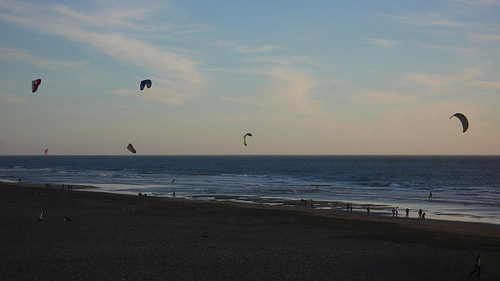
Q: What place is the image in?
A: It is at the beach.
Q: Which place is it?
A: It is a beach.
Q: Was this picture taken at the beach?
A: Yes, it was taken in the beach.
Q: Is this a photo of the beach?
A: Yes, it is showing the beach.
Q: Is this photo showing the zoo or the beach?
A: It is showing the beach.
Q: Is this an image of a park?
A: No, the picture is showing a beach.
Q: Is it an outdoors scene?
A: Yes, it is outdoors.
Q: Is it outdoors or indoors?
A: It is outdoors.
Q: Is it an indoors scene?
A: No, it is outdoors.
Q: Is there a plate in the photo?
A: Yes, there is a plate.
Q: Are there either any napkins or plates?
A: Yes, there is a plate.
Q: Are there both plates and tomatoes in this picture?
A: No, there is a plate but no tomatoes.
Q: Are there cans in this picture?
A: No, there are no cans.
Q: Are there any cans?
A: No, there are no cans.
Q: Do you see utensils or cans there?
A: No, there are no cans or utensils.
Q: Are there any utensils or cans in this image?
A: No, there are no cans or utensils.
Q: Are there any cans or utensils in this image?
A: No, there are no cans or utensils.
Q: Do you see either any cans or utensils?
A: No, there are no cans or utensils.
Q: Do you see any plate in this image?
A: Yes, there is a plate.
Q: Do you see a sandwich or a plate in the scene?
A: Yes, there is a plate.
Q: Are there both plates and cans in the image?
A: No, there is a plate but no cans.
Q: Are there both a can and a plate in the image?
A: No, there is a plate but no cans.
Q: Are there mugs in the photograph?
A: No, there are no mugs.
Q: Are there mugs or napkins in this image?
A: No, there are no mugs or napkins.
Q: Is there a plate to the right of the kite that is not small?
A: Yes, there is a plate to the right of the kite.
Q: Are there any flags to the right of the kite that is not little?
A: No, there is a plate to the right of the kite.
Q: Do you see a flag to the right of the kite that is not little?
A: No, there is a plate to the right of the kite.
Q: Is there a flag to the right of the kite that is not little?
A: No, there is a plate to the right of the kite.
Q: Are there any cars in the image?
A: No, there are no cars.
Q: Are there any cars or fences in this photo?
A: No, there are no cars or fences.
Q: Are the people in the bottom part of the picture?
A: Yes, the people are in the bottom of the image.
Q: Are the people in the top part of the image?
A: No, the people are in the bottom of the image.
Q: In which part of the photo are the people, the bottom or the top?
A: The people are in the bottom of the image.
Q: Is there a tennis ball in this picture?
A: No, there are no tennis balls.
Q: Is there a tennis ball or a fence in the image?
A: No, there are no tennis balls or fences.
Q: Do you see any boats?
A: No, there are no boats.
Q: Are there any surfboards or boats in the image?
A: No, there are no boats or surfboards.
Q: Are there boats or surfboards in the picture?
A: No, there are no boats or surfboards.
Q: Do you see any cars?
A: No, there are no cars.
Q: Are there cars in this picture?
A: No, there are no cars.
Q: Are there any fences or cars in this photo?
A: No, there are no cars or fences.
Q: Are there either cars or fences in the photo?
A: No, there are no cars or fences.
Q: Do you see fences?
A: No, there are no fences.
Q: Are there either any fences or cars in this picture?
A: No, there are no fences or cars.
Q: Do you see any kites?
A: Yes, there is a kite.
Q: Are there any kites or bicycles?
A: Yes, there is a kite.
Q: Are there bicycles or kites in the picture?
A: Yes, there is a kite.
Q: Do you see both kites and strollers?
A: No, there is a kite but no strollers.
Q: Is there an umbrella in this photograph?
A: No, there are no umbrellas.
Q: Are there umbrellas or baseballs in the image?
A: No, there are no umbrellas or baseballs.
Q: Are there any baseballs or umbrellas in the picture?
A: No, there are no umbrellas or baseballs.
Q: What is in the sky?
A: The kite is in the sky.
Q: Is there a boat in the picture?
A: No, there are no boats.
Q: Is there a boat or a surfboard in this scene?
A: No, there are no boats or surfboards.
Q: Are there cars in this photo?
A: No, there are no cars.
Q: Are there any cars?
A: No, there are no cars.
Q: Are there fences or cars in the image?
A: No, there are no cars or fences.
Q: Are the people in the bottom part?
A: Yes, the people are in the bottom of the image.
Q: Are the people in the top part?
A: No, the people are in the bottom of the image.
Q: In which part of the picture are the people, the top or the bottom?
A: The people are in the bottom of the image.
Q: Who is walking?
A: The people are walking.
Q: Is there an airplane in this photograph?
A: No, there are no airplanes.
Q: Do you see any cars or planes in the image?
A: No, there are no planes or cars.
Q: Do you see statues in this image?
A: No, there are no statues.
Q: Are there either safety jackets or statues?
A: No, there are no statues or safety jackets.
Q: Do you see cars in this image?
A: No, there are no cars.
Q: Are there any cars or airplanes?
A: No, there are no cars or airplanes.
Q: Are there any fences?
A: No, there are no fences.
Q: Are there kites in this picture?
A: Yes, there is a kite.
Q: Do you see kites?
A: Yes, there is a kite.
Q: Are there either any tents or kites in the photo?
A: Yes, there is a kite.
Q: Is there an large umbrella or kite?
A: Yes, there is a large kite.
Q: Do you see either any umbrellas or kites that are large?
A: Yes, the kite is large.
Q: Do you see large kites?
A: Yes, there is a large kite.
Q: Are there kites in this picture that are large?
A: Yes, there is a kite that is large.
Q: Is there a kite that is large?
A: Yes, there is a kite that is large.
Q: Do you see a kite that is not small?
A: Yes, there is a large kite.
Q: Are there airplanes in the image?
A: No, there are no airplanes.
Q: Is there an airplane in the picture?
A: No, there are no airplanes.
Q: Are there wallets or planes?
A: No, there are no planes or wallets.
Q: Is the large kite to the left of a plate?
A: Yes, the kite is to the left of a plate.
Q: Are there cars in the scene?
A: No, there are no cars.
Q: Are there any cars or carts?
A: No, there are no cars or carts.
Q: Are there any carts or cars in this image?
A: No, there are no cars or carts.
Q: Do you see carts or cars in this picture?
A: No, there are no cars or carts.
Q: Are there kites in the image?
A: Yes, there is a kite.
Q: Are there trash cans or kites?
A: Yes, there is a kite.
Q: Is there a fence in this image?
A: No, there are no fences.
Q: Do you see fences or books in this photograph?
A: No, there are no fences or books.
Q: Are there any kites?
A: Yes, there is a kite.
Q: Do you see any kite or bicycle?
A: Yes, there is a kite.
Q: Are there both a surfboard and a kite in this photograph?
A: No, there is a kite but no surfboards.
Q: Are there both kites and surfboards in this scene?
A: No, there is a kite but no surfboards.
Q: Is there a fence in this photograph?
A: No, there are no fences.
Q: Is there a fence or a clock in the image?
A: No, there are no fences or clocks.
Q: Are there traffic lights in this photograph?
A: No, there are no traffic lights.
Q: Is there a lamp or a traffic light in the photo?
A: No, there are no traffic lights or lamps.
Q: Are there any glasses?
A: No, there are no glasses.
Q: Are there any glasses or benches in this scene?
A: No, there are no glasses or benches.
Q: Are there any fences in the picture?
A: No, there are no fences.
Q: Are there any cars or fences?
A: No, there are no fences or cars.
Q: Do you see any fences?
A: No, there are no fences.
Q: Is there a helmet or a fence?
A: No, there are no fences or helmets.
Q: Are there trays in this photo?
A: No, there are no trays.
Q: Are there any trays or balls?
A: No, there are no trays or balls.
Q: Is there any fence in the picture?
A: No, there are no fences.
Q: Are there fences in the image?
A: No, there are no fences.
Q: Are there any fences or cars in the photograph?
A: No, there are no fences or cars.